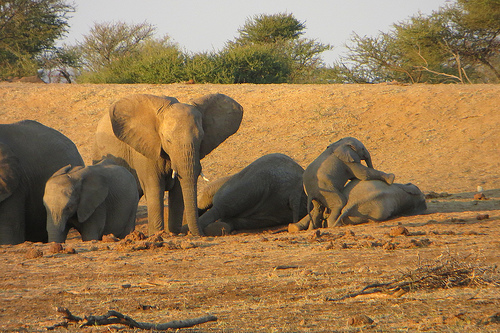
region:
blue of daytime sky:
[61, 1, 461, 61]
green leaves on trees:
[3, 3, 498, 83]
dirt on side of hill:
[1, 82, 495, 185]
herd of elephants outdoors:
[0, 92, 425, 242]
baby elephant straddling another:
[299, 134, 393, 229]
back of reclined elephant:
[338, 178, 422, 225]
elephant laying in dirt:
[199, 154, 306, 235]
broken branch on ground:
[59, 311, 216, 331]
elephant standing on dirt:
[93, 92, 245, 241]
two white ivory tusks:
[169, 168, 210, 182]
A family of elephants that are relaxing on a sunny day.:
[0, 75, 432, 260]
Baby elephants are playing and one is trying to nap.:
[290, 124, 435, 240]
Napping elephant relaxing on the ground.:
[197, 147, 306, 232]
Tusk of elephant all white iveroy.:
[154, 164, 186, 187]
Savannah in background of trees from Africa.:
[84, 27, 303, 92]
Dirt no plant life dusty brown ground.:
[395, 95, 477, 162]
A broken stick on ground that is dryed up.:
[47, 293, 229, 332]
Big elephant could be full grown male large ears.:
[91, 91, 247, 241]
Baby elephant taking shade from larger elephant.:
[41, 153, 143, 258]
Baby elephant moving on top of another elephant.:
[315, 139, 395, 181]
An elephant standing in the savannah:
[91, 92, 242, 238]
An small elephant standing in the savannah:
[40, 161, 140, 241]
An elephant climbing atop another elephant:
[300, 136, 422, 230]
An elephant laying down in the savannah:
[195, 152, 309, 237]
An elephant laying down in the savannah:
[288, 178, 425, 233]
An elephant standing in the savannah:
[0, 118, 81, 242]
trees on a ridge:
[2, 0, 498, 82]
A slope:
[0, 80, 498, 194]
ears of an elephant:
[108, 92, 243, 159]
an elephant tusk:
[169, 168, 176, 178]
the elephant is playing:
[286, 110, 383, 250]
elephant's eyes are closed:
[140, 113, 209, 159]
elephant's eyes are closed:
[154, 115, 233, 172]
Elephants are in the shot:
[0, 80, 436, 252]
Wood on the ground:
[46, 287, 251, 332]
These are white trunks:
[160, 162, 220, 199]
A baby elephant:
[295, 135, 401, 225]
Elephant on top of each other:
[293, 128, 433, 234]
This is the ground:
[205, 251, 336, 310]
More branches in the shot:
[341, 241, 483, 310]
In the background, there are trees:
[6, 3, 498, 86]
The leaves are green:
[81, 16, 265, 81]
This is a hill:
[8, 67, 499, 158]